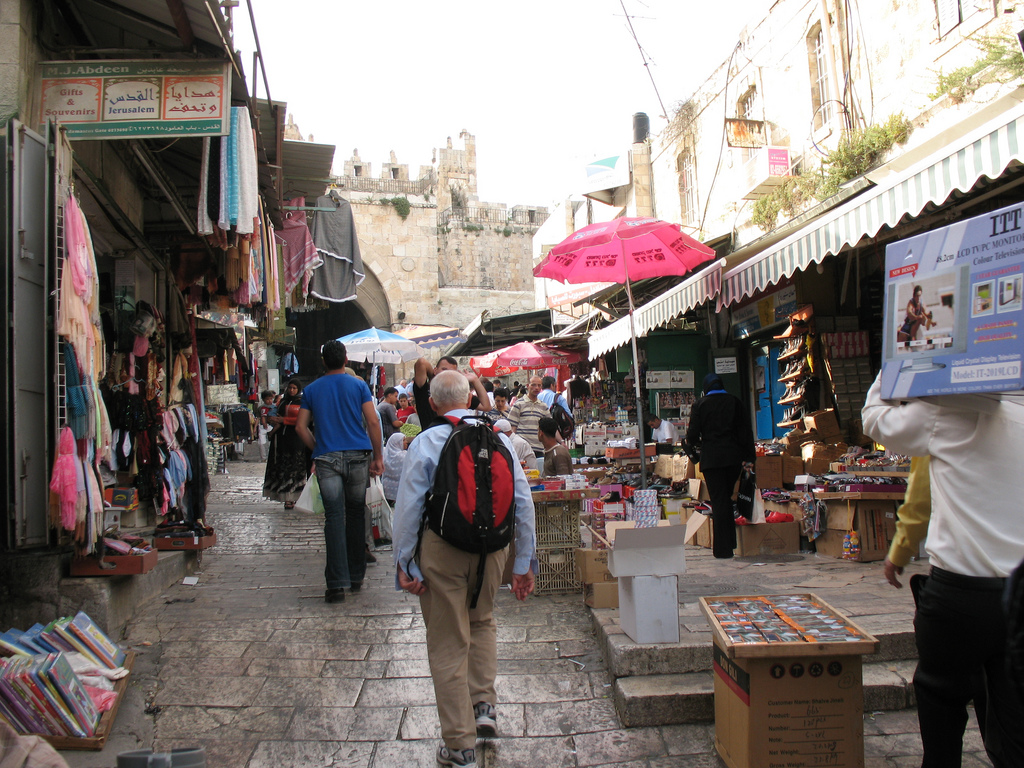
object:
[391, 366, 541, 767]
man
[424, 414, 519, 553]
backback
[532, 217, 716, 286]
umbrella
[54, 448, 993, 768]
street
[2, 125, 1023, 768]
vendors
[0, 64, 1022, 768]
things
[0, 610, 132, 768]
items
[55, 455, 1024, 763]
ground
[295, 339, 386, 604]
man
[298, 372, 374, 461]
shirt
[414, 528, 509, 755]
slacks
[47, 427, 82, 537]
scarf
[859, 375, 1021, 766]
man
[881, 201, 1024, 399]
box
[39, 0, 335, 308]
roof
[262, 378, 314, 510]
woman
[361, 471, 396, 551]
shopping bag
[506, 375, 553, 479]
man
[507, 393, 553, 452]
shirt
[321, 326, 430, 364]
umbrella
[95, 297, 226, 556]
clothing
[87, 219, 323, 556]
sale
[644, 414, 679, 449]
man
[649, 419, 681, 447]
shirt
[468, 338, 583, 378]
umbrella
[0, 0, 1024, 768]
market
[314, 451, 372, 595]
jeans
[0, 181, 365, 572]
display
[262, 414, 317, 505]
skirt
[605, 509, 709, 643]
packages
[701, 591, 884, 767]
box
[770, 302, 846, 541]
shoes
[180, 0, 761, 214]
sky